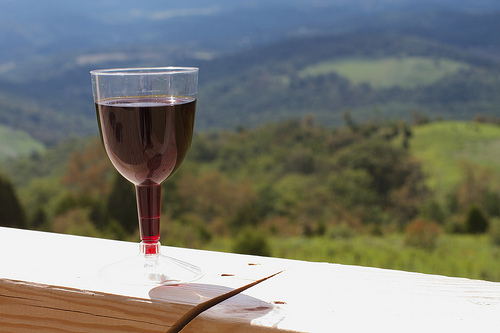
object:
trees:
[0, 0, 499, 258]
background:
[0, 0, 499, 282]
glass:
[90, 66, 203, 286]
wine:
[95, 98, 196, 255]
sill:
[0, 225, 499, 332]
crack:
[167, 270, 284, 332]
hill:
[0, 121, 499, 235]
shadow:
[148, 283, 273, 332]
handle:
[137, 185, 160, 255]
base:
[109, 254, 205, 285]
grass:
[0, 0, 499, 282]